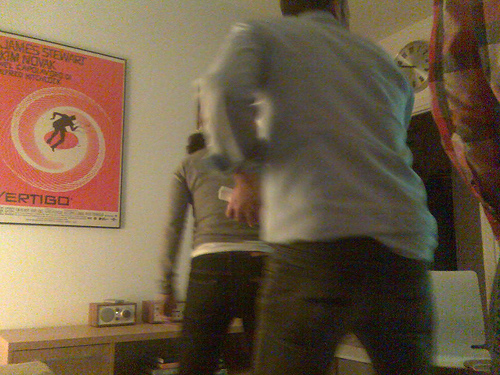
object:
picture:
[0, 27, 130, 229]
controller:
[216, 183, 262, 208]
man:
[195, 12, 442, 375]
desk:
[0, 305, 253, 375]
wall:
[4, 0, 238, 328]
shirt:
[198, 10, 445, 263]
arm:
[153, 160, 190, 318]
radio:
[141, 298, 186, 324]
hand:
[226, 170, 267, 228]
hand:
[155, 290, 179, 318]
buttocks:
[257, 246, 439, 338]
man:
[176, 125, 280, 373]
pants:
[253, 227, 459, 373]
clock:
[380, 31, 437, 95]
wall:
[344, 12, 498, 367]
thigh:
[177, 250, 234, 374]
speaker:
[87, 295, 142, 332]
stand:
[0, 311, 251, 375]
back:
[256, 20, 422, 244]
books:
[141, 350, 176, 373]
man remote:
[195, 15, 462, 230]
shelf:
[0, 313, 249, 375]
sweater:
[154, 143, 267, 298]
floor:
[0, 338, 500, 375]